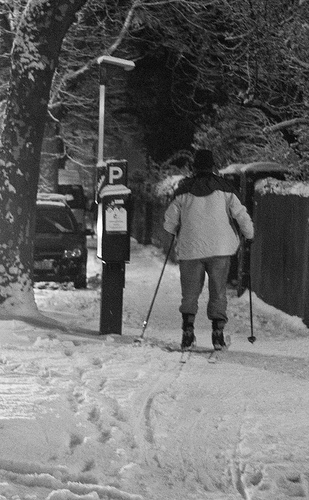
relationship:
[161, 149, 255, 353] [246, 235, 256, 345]
man skiing ski pole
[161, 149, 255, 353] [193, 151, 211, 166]
man skiing hat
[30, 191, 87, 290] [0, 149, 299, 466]
car facing camera.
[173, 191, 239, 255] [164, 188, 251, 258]
back of winter coat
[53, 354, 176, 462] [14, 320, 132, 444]
marks on ground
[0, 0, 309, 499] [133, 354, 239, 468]
snow on ground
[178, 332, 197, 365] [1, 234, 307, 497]
skis on ground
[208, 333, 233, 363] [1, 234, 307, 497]
skis on ground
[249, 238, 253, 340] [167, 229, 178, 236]
pole in hand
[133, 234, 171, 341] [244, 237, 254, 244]
ski pole in hand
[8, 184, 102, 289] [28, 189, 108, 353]
car in snow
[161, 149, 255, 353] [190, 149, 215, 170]
man wearing hat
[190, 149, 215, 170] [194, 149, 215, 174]
hat on head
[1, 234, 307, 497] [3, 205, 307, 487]
ground covered in snow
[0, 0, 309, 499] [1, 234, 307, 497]
snow on ground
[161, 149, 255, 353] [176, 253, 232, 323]
man wearing pants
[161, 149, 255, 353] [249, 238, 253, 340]
man holding pole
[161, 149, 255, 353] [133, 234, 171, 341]
man holding ski pole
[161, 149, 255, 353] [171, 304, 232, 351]
man wearing boots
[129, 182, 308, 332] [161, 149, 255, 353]
fence to right of man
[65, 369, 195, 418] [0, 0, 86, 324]
snow on tree trnk